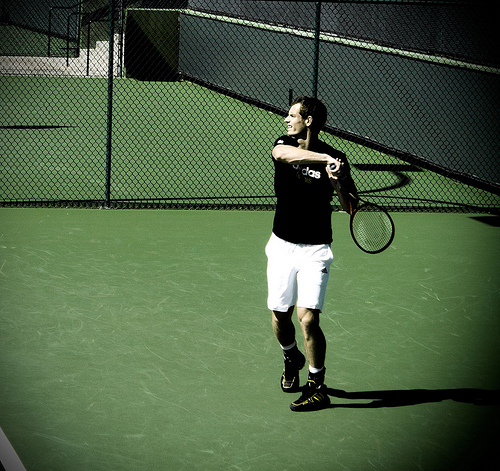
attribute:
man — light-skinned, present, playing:
[254, 94, 359, 412]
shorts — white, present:
[262, 232, 337, 313]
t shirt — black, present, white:
[271, 138, 352, 243]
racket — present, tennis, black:
[343, 189, 395, 256]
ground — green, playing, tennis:
[1, 76, 496, 464]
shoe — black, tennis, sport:
[292, 383, 335, 415]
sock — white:
[278, 341, 300, 357]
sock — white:
[307, 365, 327, 381]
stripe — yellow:
[311, 392, 321, 403]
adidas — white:
[289, 162, 326, 183]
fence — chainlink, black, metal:
[1, 1, 497, 212]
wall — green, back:
[181, 1, 498, 192]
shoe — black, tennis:
[274, 352, 305, 394]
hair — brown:
[290, 94, 327, 131]